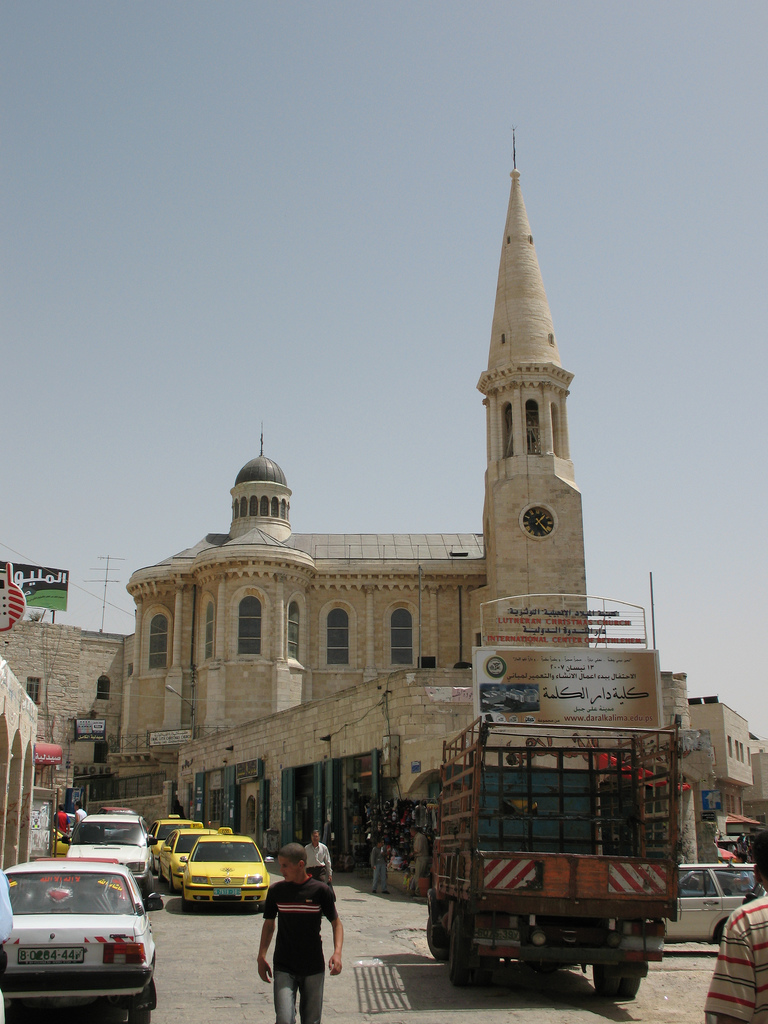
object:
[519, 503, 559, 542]
clock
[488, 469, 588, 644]
stone wall